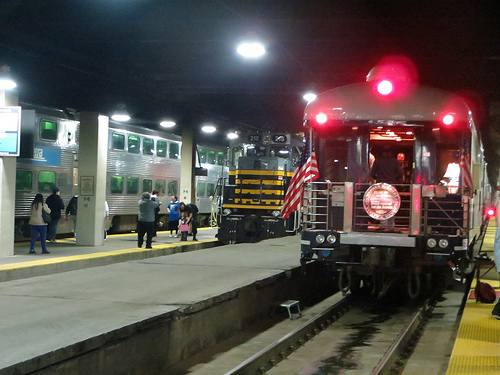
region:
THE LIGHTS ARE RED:
[304, 62, 465, 146]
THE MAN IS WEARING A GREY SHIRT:
[133, 197, 167, 230]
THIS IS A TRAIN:
[298, 44, 495, 318]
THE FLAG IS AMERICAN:
[268, 137, 324, 229]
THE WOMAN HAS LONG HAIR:
[28, 192, 48, 212]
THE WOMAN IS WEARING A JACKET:
[24, 200, 52, 230]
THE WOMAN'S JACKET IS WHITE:
[27, 197, 57, 231]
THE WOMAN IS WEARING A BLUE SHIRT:
[161, 201, 183, 225]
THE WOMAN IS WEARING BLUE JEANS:
[26, 221, 50, 256]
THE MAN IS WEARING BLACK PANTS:
[131, 217, 161, 250]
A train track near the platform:
[167, 290, 418, 372]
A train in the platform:
[280, 50, 495, 335]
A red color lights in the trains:
[290, 70, 470, 160]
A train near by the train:
[205, 122, 290, 267]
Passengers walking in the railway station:
[30, 172, 212, 267]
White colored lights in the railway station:
[0, 40, 285, 150]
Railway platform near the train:
[5, 230, 295, 346]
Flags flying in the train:
[283, 160, 339, 221]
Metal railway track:
[263, 296, 453, 373]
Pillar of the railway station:
[65, 113, 128, 255]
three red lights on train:
[305, 72, 475, 140]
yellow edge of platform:
[439, 327, 491, 364]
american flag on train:
[272, 132, 321, 227]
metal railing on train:
[303, 179, 428, 229]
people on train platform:
[125, 190, 199, 245]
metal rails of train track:
[270, 323, 430, 359]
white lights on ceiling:
[154, 114, 239, 141]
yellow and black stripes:
[228, 164, 287, 210]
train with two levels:
[108, 132, 140, 216]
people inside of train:
[374, 147, 409, 178]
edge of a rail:
[387, 314, 408, 349]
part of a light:
[433, 106, 457, 133]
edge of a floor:
[135, 281, 205, 332]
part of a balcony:
[389, 190, 434, 249]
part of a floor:
[95, 272, 127, 303]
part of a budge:
[346, 177, 392, 221]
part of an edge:
[200, 279, 254, 303]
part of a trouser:
[128, 217, 149, 239]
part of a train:
[380, 87, 445, 153]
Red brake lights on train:
[303, 71, 462, 136]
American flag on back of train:
[285, 131, 326, 226]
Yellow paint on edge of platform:
[9, 246, 120, 271]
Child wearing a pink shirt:
[179, 218, 193, 243]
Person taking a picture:
[135, 191, 167, 246]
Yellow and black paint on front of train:
[223, 158, 285, 211]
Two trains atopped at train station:
[219, 135, 452, 300]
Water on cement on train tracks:
[318, 307, 383, 372]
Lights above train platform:
[107, 96, 242, 153]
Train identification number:
[244, 132, 261, 144]